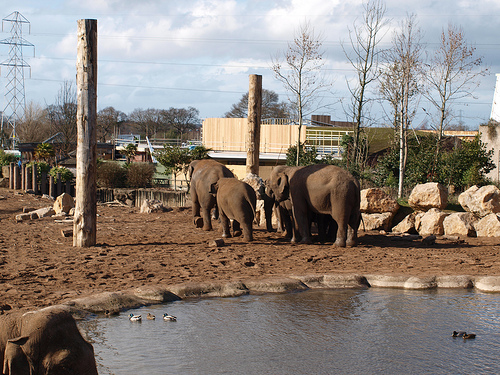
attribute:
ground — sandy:
[1, 186, 499, 314]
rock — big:
[469, 210, 499, 240]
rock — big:
[455, 182, 498, 214]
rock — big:
[440, 207, 477, 237]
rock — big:
[407, 202, 455, 239]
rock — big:
[357, 186, 401, 213]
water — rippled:
[73, 287, 499, 371]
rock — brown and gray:
[353, 183, 401, 207]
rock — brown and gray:
[355, 210, 400, 233]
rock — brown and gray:
[404, 177, 447, 209]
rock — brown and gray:
[412, 205, 452, 236]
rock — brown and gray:
[437, 205, 479, 237]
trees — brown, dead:
[272, 10, 473, 197]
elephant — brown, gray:
[261, 154, 362, 241]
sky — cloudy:
[2, 3, 498, 141]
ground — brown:
[1, 163, 497, 306]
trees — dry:
[333, 1, 427, 179]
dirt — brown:
[2, 170, 496, 308]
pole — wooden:
[72, 14, 102, 248]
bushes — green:
[342, 124, 492, 191]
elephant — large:
[182, 163, 231, 243]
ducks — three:
[125, 305, 183, 325]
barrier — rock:
[69, 261, 497, 318]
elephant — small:
[211, 173, 258, 238]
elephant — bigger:
[178, 154, 238, 232]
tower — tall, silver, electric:
[3, 5, 39, 165]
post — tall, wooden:
[60, 14, 101, 248]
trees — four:
[278, 9, 494, 195]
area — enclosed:
[2, 152, 496, 371]